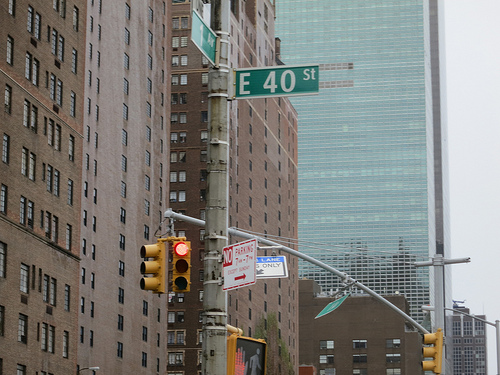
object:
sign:
[231, 63, 318, 100]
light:
[172, 238, 191, 260]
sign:
[216, 237, 262, 292]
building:
[2, 1, 86, 372]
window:
[69, 46, 80, 75]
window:
[373, 265, 382, 273]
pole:
[197, 0, 233, 372]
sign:
[227, 334, 269, 374]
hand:
[232, 344, 248, 373]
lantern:
[138, 236, 169, 297]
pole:
[161, 204, 445, 336]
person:
[246, 344, 262, 373]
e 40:
[238, 68, 298, 96]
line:
[422, 3, 440, 337]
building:
[274, 3, 455, 374]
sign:
[186, 10, 220, 67]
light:
[420, 324, 443, 372]